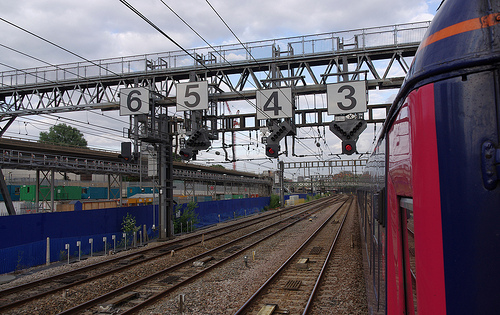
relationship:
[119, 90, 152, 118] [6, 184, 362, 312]
number above track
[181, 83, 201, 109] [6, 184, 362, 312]
five above track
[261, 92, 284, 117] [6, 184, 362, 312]
four above track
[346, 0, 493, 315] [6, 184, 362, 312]
train on track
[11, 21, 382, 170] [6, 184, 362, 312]
power lines above track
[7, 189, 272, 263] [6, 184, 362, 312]
fence next to track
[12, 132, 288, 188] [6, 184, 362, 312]
bridge next to track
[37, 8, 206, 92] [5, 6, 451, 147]
clouds in sky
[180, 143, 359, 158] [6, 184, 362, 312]
lights above track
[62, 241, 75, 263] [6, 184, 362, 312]
pole next to track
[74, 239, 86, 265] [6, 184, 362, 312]
pole next to track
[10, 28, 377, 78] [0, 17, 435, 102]
rails on walkway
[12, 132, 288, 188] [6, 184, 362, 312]
bridge by track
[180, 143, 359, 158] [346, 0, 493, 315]
lights for train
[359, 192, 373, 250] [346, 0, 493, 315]
window on train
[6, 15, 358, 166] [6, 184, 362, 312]
wires above track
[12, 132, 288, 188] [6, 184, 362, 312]
bridge over track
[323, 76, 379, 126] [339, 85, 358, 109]
sign has three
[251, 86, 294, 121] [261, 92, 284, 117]
sign has four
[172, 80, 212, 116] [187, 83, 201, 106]
sign has five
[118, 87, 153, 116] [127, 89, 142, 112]
sign has six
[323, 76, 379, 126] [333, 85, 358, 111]
sign has three